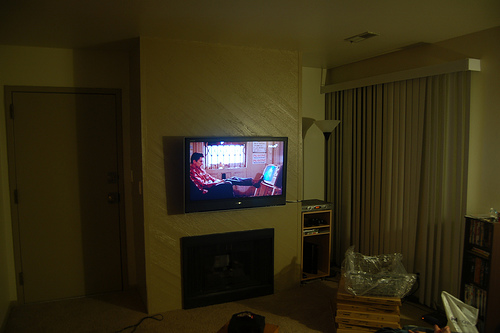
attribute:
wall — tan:
[136, 56, 374, 304]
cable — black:
[126, 311, 159, 326]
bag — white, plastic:
[427, 287, 494, 331]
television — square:
[165, 133, 291, 220]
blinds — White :
[327, 58, 484, 296]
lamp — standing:
[312, 115, 339, 199]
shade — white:
[312, 116, 342, 135]